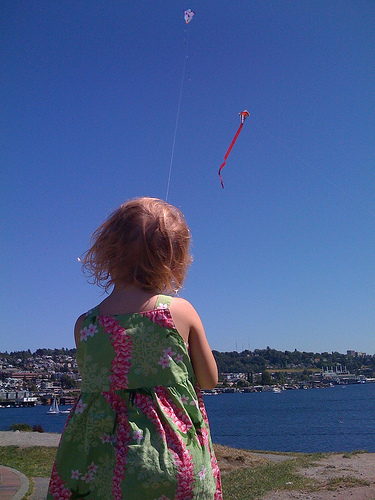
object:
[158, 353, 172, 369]
flower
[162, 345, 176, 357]
flower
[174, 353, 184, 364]
flower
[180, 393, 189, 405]
flower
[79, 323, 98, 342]
flower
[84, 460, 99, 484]
flower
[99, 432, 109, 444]
flower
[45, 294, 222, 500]
dress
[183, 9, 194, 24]
kite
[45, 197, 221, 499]
child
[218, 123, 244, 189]
tail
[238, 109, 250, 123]
kite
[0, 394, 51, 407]
harbour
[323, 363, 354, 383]
buildings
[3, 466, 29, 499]
brick path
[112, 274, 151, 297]
neck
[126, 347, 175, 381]
back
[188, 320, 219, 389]
arm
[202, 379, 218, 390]
elbow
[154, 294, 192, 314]
shoulder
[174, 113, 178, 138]
string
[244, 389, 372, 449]
water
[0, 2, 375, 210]
sky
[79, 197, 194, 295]
hair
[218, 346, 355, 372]
trees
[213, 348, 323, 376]
mountain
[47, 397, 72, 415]
boat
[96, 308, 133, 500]
flowers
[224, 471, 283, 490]
grass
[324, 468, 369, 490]
dirt